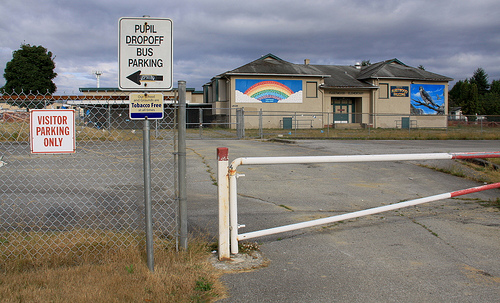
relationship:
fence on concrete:
[7, 82, 194, 267] [1, 136, 498, 300]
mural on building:
[235, 79, 304, 103] [184, 48, 470, 140]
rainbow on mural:
[241, 80, 292, 103] [234, 78, 304, 107]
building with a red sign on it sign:
[205, 54, 449, 129] [333, 104, 350, 113]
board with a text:
[117, 17, 174, 92] [55, 100, 70, 205]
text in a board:
[125, 22, 165, 68] [115, 17, 175, 92]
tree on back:
[8, 22, 74, 127] [449, 53, 455, 100]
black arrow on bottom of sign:
[125, 69, 163, 85] [118, 16, 173, 94]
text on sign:
[126, 22, 164, 67] [119, 14, 169, 89]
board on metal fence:
[117, 17, 174, 92] [70, 167, 120, 259]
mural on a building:
[304, 72, 314, 148] [210, 48, 341, 135]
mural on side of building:
[408, 84, 443, 119] [225, 65, 244, 114]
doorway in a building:
[326, 96, 355, 123] [190, 43, 465, 142]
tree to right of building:
[447, 76, 464, 112] [205, 54, 449, 129]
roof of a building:
[230, 53, 452, 80] [205, 54, 449, 129]